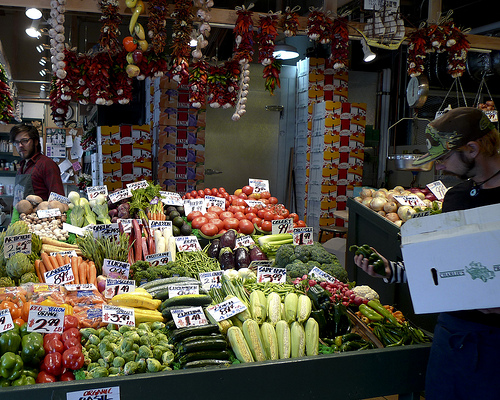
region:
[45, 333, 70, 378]
a group of red peppers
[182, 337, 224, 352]
a pair of green cucumbers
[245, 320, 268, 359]
a yellow ear of corn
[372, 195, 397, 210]
two yellow onions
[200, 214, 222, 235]
two red tomatoes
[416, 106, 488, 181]
face of a man with a hat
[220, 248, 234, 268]
one purple eggplant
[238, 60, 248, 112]
garlic hanging from the ceiling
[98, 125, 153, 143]
a box of produce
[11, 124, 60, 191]
a produce clerk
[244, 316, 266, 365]
a single ear of corn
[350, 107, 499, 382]
a man picking out a pepper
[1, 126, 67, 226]
a man wearing an apron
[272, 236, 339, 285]
heads of brocolee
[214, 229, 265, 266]
purple eggplant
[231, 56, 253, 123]
a bunch of garlic hanging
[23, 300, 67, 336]
a price sign for green and red peppers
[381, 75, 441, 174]
a produce scale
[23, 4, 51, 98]
track lighting that is turned on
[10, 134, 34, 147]
a pair of men's black glasses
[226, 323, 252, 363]
an ear of corn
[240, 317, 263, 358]
an ear of corn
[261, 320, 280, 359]
an ear of corn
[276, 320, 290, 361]
an ear of corn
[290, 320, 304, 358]
an ear of corn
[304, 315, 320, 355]
an ear of corn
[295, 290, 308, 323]
an ear of corn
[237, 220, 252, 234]
a ripe red tomato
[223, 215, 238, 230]
a ripe red tomato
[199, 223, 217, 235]
a ripe red tomato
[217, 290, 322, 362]
Fresh ears of corn.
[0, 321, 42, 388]
Pile of green peppers.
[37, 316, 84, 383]
Pile of red peppers.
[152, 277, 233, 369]
Horizontally stacked cucumbers with sign.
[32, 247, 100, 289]
Stack of carrots with sign.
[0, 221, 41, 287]
Pile of green artichokes.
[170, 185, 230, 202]
Pile of red tomatoes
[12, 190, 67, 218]
Bile of large mushrooms.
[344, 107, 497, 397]
Man holding a pepper.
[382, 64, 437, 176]
Metal basket scale hanging form ceiling.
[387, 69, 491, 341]
man holding a box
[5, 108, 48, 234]
man wearing an apron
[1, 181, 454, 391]
vegetables in the box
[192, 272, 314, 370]
the vegetable is corn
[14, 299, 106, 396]
vegetable is a red pepper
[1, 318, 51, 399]
vegetable is a green pepper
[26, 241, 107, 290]
vegetable is a carrot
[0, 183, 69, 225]
vegetable is a potato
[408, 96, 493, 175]
man wearing a hat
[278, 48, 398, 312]
boxes stacked in background